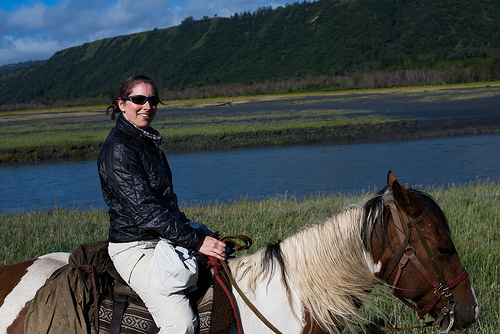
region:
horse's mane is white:
[258, 183, 399, 313]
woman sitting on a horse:
[78, 38, 247, 331]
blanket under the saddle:
[87, 246, 237, 332]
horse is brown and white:
[209, 174, 498, 328]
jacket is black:
[79, 111, 209, 258]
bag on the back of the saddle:
[3, 239, 97, 331]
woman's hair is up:
[102, 69, 167, 126]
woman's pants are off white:
[104, 223, 232, 331]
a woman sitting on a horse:
[65, 73, 436, 313]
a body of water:
[240, 119, 451, 184]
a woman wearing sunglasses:
[116, 75, 166, 121]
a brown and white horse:
[221, 222, 407, 331]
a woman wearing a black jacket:
[75, 128, 176, 228]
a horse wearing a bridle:
[375, 212, 459, 304]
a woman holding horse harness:
[193, 226, 251, 263]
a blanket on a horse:
[100, 290, 215, 332]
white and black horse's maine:
[319, 193, 388, 267]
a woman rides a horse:
[15, 60, 482, 328]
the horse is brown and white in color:
[12, 177, 477, 332]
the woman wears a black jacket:
[95, 115, 207, 245]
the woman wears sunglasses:
[124, 92, 163, 104]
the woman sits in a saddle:
[100, 235, 245, 317]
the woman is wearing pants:
[102, 244, 197, 332]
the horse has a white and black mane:
[242, 193, 450, 329]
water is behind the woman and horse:
[7, 120, 497, 212]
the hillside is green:
[33, 4, 496, 103]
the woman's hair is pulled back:
[103, 66, 159, 118]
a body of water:
[235, 120, 470, 207]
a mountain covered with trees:
[9, 21, 458, 80]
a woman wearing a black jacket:
[99, 133, 184, 232]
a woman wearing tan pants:
[120, 234, 154, 318]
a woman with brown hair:
[115, 67, 162, 133]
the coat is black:
[117, 154, 138, 184]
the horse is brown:
[413, 233, 427, 261]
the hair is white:
[316, 246, 344, 275]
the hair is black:
[416, 189, 439, 214]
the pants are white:
[126, 257, 151, 285]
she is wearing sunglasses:
[136, 93, 156, 104]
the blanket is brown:
[131, 311, 143, 326]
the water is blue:
[278, 162, 308, 184]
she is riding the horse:
[96, 234, 185, 309]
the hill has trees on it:
[156, 53, 181, 74]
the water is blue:
[297, 156, 364, 190]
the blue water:
[226, 168, 256, 200]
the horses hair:
[309, 253, 346, 291]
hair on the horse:
[301, 249, 341, 278]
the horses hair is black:
[262, 242, 282, 260]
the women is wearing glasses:
[132, 92, 161, 105]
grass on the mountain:
[262, 26, 321, 57]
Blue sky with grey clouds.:
[1, 0, 299, 66]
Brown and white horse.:
[0, 170, 477, 332]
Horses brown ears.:
[386, 169, 413, 216]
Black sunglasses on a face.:
[119, 95, 160, 105]